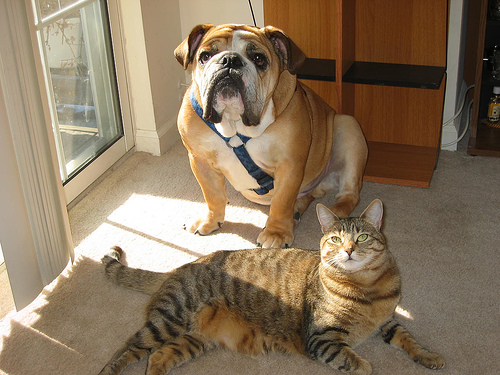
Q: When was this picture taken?
A: During the day.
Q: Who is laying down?
A: The cat.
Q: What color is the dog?
A: Brown.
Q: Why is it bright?
A: It's sunny.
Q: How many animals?
A: Two.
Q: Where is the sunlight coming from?
A: The window.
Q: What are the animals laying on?
A: Carpet.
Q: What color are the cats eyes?
A: Green.